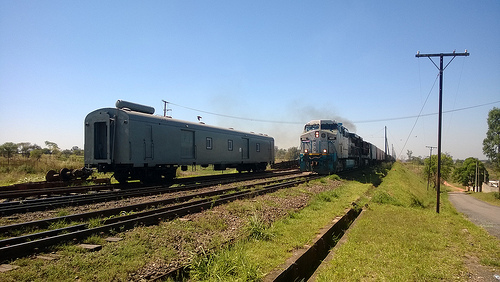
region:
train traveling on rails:
[288, 111, 400, 173]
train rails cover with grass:
[9, 180, 410, 277]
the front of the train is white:
[287, 113, 347, 164]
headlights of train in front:
[302, 143, 330, 158]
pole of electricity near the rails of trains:
[405, 43, 474, 218]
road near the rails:
[453, 187, 498, 227]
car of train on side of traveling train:
[73, 91, 403, 195]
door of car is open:
[88, 111, 121, 167]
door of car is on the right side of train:
[101, 110, 116, 170]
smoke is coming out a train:
[282, 96, 369, 176]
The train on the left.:
[0, 86, 331, 191]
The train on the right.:
[293, 110, 401, 184]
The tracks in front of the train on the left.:
[14, 177, 115, 201]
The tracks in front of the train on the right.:
[0, 165, 319, 222]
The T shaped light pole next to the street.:
[418, 42, 463, 216]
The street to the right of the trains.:
[444, 171, 499, 244]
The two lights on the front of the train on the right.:
[301, 145, 328, 155]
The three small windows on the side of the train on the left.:
[198, 137, 272, 164]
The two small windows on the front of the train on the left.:
[302, 120, 343, 130]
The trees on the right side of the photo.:
[412, 101, 499, 176]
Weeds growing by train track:
[204, 253, 259, 277]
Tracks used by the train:
[140, 207, 185, 222]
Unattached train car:
[75, 102, 279, 176]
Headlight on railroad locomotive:
[315, 127, 320, 145]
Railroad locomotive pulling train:
[300, 117, 355, 177]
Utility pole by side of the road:
[411, 49, 469, 219]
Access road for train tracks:
[445, 183, 493, 224]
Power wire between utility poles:
[383, 109, 432, 122]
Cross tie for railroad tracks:
[69, 236, 102, 256]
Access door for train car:
[90, 111, 113, 162]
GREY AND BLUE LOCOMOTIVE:
[282, 113, 386, 173]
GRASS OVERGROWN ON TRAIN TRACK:
[96, 175, 406, 265]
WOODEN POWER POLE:
[408, 29, 465, 196]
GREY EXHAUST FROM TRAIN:
[245, 85, 359, 136]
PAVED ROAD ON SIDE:
[442, 181, 499, 234]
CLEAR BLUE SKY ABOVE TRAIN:
[0, 2, 486, 157]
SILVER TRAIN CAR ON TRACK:
[95, 107, 280, 177]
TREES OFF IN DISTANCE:
[0, 128, 88, 160]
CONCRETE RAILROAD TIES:
[8, 167, 328, 237]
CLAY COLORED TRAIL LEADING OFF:
[436, 174, 469, 196]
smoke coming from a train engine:
[283, 94, 373, 171]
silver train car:
[69, 107, 277, 179]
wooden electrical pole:
[408, 23, 482, 223]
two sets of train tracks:
[172, 166, 310, 218]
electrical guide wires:
[375, 75, 436, 182]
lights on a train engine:
[301, 120, 339, 145]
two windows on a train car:
[193, 131, 236, 153]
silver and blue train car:
[283, 111, 370, 181]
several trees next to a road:
[440, 152, 487, 207]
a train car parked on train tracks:
[79, 96, 284, 173]